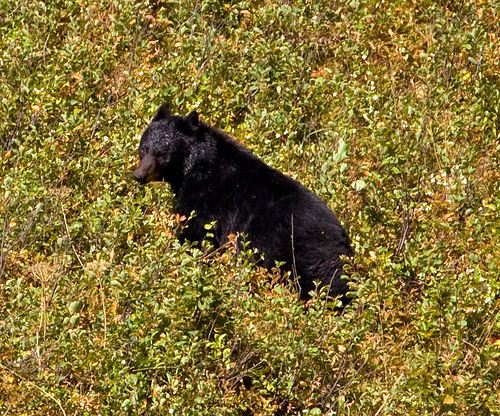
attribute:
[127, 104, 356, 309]
bear — black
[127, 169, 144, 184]
nose — little, black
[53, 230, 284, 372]
plants — green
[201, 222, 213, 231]
leaf — green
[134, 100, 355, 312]
dog — black, small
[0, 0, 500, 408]
shrubs — prickly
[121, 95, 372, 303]
bear — sitting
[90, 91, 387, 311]
bear — black 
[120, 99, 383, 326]
bear — black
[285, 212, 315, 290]
twig — thin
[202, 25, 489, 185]
stems — brown 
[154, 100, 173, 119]
ear — pointy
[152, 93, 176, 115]
ear — black 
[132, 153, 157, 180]
snout — brown, long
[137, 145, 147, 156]
eye — small, black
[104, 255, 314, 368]
grass — green, short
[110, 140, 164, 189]
nose — black 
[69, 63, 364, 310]
bear — furry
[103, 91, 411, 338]
dog — black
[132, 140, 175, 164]
eye — black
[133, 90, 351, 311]
bear — black